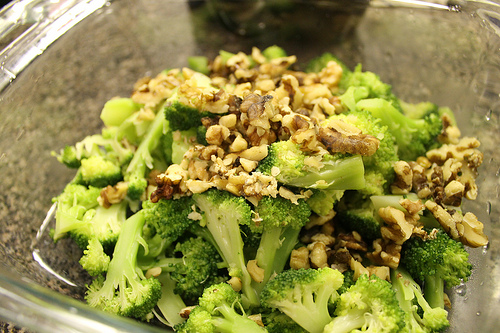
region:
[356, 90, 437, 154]
The broccoli is green.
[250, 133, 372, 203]
The broccoli is green.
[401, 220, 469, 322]
The broccoli is green.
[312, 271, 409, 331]
The broccoli is green.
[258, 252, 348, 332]
The broccoli is green.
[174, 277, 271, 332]
The broccoli is green.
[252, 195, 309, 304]
The broccoli is green.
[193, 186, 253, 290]
The broccoli is green.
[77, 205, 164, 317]
The broccoli is green.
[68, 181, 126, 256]
The broccoli is green.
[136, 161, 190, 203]
Nuts atop of green veggie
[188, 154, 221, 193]
Nuts atop of green veggie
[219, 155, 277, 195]
Nuts atop of green veggie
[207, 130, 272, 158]
Nuts atop of green veggie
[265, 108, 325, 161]
Nuts atop of green veggie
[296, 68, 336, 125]
Nuts atop of green veggie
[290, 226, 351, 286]
Nuts atop of green veggie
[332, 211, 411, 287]
Nuts atop of green veggie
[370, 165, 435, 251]
Nuts atop of green veggie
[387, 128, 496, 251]
Nuts atop of green veggie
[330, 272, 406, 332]
a green broccoli floret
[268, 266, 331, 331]
a green broccoli floret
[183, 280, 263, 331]
a green broccoli floret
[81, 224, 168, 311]
a green broccoli floret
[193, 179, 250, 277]
a green broccoli floret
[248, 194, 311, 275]
a green broccoli floret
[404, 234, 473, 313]
a green broccoli floret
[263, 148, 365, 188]
a green broccoli floret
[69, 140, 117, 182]
a green broccoli floret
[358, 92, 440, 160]
a green broccoli floret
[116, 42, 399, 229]
nuts on top of broccoli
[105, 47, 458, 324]
chopped pieces of broccoli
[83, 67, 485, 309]
broccoli with nuts on top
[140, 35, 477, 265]
chopped pieces of nuts on broccoli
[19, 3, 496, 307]
a clear bowl of food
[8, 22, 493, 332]
a clear bowl of broccoli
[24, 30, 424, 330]
a bowl of broccoli and nuts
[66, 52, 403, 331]
green broccoli and brown nuts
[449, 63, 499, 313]
water drops on side of dish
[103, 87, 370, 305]
a broccoli and nut mixture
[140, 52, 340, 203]
Tan nuts on top of broccoli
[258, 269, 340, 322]
Broccoli on bottom of pile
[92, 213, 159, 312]
Broccoli floret in container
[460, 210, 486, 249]
Nut on edge of pile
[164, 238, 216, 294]
Head of broccoli floret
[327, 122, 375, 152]
Walnut balancing on broccoli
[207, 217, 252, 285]
Yellow broccoli stem in container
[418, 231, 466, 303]
Broccoli under tan nuts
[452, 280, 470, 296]
Water droplet on side of container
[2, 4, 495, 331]
Glass container with broccoli and nuts